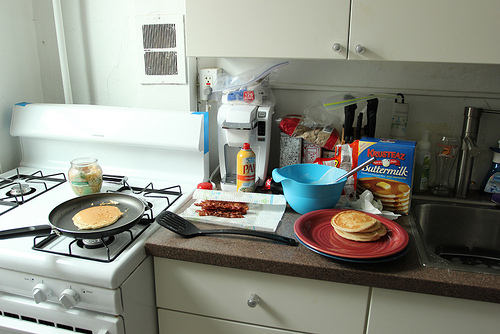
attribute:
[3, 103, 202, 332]
stove — white, new, gas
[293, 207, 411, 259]
plate — red, under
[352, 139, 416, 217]
box — blue, krusteaz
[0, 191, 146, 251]
skillet — black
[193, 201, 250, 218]
bacon — crispy, in a stack, on paper towel, drying, in paper towel, fried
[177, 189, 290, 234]
bacon — draining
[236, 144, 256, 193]
cooking spray — nonstick, non stick, red, behind bacon, pam, yellow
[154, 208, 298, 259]
th slotted turner — black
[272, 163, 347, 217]
bowl — blue, plastic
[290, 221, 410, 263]
plate — blue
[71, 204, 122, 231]
pancakes — cooked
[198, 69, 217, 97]
electric outlet — white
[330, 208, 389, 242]
pancakes — stacked, in a stack, in a plate, three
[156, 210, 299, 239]
spatula — black, plastic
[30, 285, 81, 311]
knobs — white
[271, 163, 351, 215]
pancake mix — on a bowl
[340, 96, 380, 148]
knifes — in a set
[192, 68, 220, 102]
outlet — white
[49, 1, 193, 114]
wall — white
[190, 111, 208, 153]
masking tape — blue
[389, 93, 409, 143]
paper towel — roll, behind the box